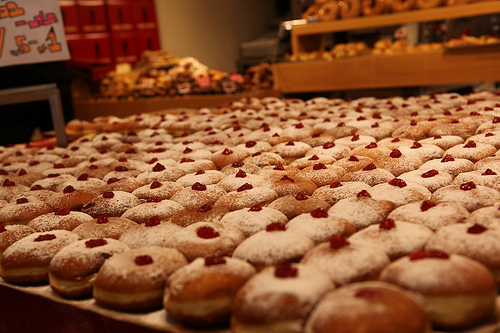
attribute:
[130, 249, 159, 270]
fruit — red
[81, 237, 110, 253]
fruit — red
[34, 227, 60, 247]
fruit — red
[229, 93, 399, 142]
fruit — red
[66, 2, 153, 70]
box — red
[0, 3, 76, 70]
sign — white, yellow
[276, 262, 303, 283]
jelly — raspberry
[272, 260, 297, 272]
jelly — raspberry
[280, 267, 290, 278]
jelly — raspberry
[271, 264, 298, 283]
jelly — raspberry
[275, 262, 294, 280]
jelly — raspberry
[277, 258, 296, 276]
jelly — raspberry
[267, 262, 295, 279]
jelly — raspberry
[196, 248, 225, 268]
jelly — raspberry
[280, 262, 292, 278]
jelly — raspberry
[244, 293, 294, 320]
pastry — one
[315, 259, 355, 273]
sugar — powdered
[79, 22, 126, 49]
container — red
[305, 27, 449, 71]
stand — display